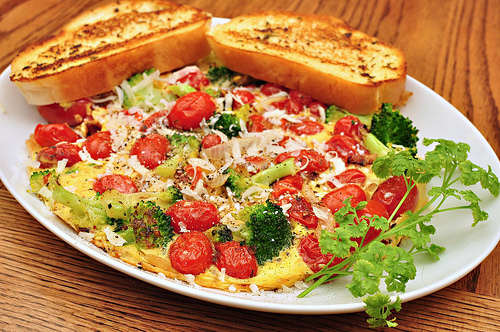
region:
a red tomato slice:
[166, 80, 219, 132]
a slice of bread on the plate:
[5, 0, 213, 107]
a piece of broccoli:
[242, 189, 294, 259]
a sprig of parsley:
[293, 130, 497, 329]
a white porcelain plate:
[0, 0, 499, 325]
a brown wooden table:
[1, 0, 498, 330]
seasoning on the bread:
[29, 9, 187, 74]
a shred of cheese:
[184, 150, 221, 170]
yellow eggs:
[28, 75, 428, 287]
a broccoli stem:
[251, 156, 307, 188]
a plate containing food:
[23, 19, 439, 316]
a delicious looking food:
[38, 21, 471, 261]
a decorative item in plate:
[336, 142, 478, 309]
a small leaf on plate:
[295, 140, 493, 328]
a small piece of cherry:
[159, 213, 226, 273]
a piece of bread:
[26, 5, 233, 123]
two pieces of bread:
[24, 0, 488, 183]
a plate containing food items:
[16, 9, 496, 324]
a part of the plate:
[257, 280, 385, 330]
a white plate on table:
[8, 7, 490, 312]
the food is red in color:
[167, 226, 214, 273]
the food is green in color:
[224, 163, 295, 198]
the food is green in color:
[372, 106, 417, 151]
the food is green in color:
[126, 200, 172, 252]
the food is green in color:
[310, 135, 492, 302]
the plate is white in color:
[4, 11, 499, 313]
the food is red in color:
[167, 91, 216, 132]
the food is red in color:
[132, 131, 172, 173]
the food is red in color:
[33, 122, 75, 147]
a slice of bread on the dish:
[212, 6, 411, 114]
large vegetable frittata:
[26, 69, 429, 296]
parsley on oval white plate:
[296, 132, 498, 329]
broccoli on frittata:
[227, 199, 292, 262]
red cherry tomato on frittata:
[167, 90, 217, 130]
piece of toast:
[208, 11, 405, 112]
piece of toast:
[12, 1, 214, 106]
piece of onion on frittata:
[198, 135, 262, 165]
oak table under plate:
[1, 0, 498, 330]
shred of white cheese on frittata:
[129, 68, 160, 94]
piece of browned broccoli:
[108, 200, 173, 251]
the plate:
[107, 145, 361, 329]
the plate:
[24, 158, 206, 329]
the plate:
[121, 184, 279, 316]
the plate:
[190, 262, 258, 322]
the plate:
[137, 92, 305, 304]